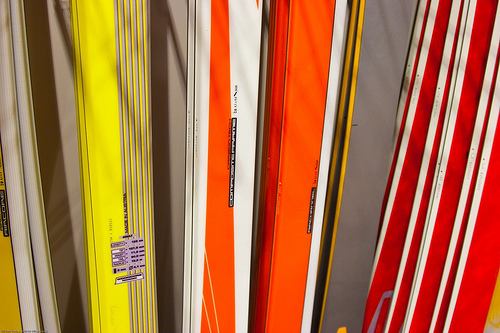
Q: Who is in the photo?
A: No one.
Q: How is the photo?
A: Clear.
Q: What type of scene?
A: Outdoor.